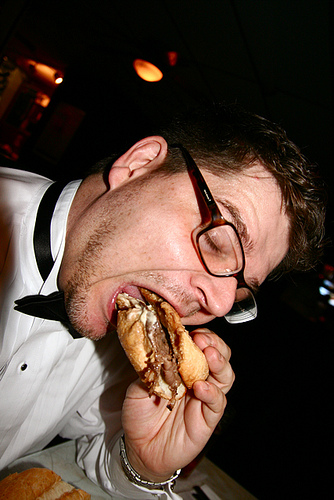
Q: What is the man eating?
A: A sandwich.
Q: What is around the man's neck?
A: A bow tie.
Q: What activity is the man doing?
A: Eating.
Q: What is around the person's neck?
A: Bow tie.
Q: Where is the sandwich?
A: Man's left hand.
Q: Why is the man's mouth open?
A: To eat food.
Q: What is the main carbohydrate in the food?
A: Bun.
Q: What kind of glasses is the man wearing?
A: Vision correction.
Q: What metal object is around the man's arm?
A: Watch.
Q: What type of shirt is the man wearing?
A: Formal dress shirt.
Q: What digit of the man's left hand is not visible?
A: Thumb.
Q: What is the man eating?
A: Hamburger.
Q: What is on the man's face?
A: Glasses.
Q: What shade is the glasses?
A: Black.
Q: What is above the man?
A: Lights.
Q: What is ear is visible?
A: Left ear.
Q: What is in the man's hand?
A: Sandwich.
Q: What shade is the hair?
A: Brown.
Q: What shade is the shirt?
A: White.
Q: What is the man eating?
A: Hamburger.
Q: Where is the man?
A: At the restaurant.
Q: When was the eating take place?
A: At night.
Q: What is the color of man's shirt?
A: White.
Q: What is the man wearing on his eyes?
A: Eyeglasses.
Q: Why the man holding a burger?
A: To eat.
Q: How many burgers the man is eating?
A: One.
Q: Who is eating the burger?
A: The man.